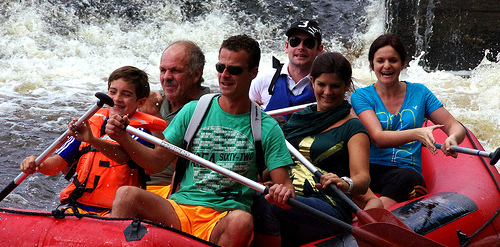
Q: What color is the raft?
A: Red.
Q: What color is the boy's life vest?
A: Orange.